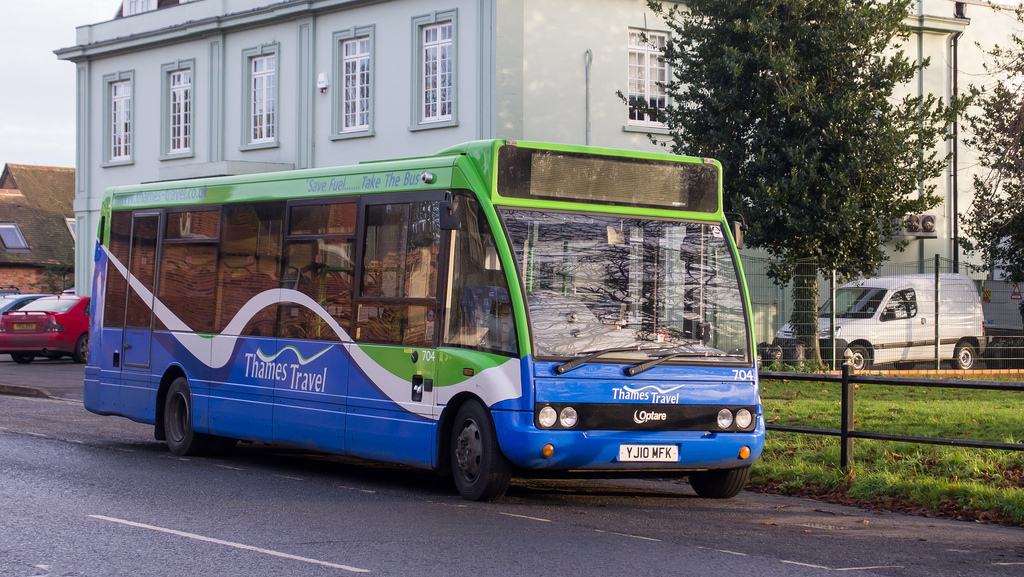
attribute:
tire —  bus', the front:
[446, 396, 501, 507]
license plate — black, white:
[619, 437, 684, 463]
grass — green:
[740, 363, 1022, 519]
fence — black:
[758, 364, 1018, 485]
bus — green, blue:
[86, 137, 767, 500]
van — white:
[781, 271, 989, 371]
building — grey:
[51, 3, 1022, 356]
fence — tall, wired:
[732, 255, 1022, 372]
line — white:
[102, 466, 260, 564]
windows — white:
[93, 13, 603, 197]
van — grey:
[795, 272, 1010, 387]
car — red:
[26, 264, 78, 379]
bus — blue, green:
[67, 21, 822, 499]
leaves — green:
[722, 104, 1018, 346]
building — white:
[58, 78, 789, 368]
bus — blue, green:
[162, 43, 696, 534]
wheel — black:
[361, 400, 524, 526]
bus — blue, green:
[93, 183, 744, 529]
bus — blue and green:
[108, 134, 748, 519]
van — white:
[777, 217, 1022, 431]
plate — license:
[592, 430, 688, 459]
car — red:
[762, 203, 991, 407]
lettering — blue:
[330, 164, 430, 193]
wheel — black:
[444, 396, 507, 498]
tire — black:
[133, 363, 213, 444]